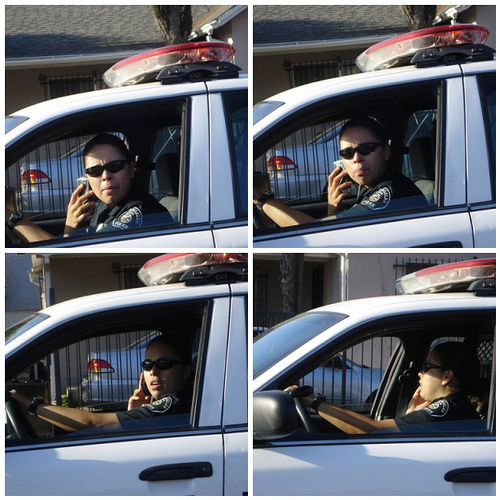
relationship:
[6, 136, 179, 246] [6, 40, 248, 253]
cop in a car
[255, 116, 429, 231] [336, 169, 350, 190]
officer on phone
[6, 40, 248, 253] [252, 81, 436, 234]
car has a window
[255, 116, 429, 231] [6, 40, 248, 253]
officer inside a car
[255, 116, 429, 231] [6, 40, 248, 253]
officer inside car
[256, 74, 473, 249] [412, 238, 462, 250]
door has a handle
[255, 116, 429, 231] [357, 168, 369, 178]
officer has teeth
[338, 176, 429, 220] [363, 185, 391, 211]
uniform has a patch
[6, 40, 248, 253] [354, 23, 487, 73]
car has a lighs